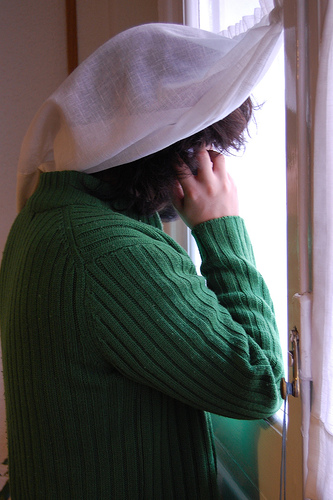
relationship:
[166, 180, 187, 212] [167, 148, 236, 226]
thumb on hand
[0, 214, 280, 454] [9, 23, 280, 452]
sweater on woman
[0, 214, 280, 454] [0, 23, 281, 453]
sweater on man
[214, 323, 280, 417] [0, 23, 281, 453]
elbow of man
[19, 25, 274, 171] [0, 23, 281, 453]
curtain over man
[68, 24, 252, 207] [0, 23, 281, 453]
head of man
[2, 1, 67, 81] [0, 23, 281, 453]
wall behind man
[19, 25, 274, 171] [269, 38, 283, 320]
drape on window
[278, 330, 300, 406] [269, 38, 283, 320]
handle on window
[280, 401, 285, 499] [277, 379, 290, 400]
ribbon on knob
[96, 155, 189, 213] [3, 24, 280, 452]
hair on person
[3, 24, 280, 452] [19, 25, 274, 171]
person under drape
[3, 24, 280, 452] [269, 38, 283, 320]
person looking out window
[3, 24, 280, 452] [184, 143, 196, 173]
person holding phone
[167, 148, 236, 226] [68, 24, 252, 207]
hand to head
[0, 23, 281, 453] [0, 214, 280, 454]
man wearing a sweater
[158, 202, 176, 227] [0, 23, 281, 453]
beard on man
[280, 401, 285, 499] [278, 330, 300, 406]
ribbon hanging from handle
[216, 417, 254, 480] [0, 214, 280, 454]
shadow from sweater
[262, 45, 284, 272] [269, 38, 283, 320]
light in window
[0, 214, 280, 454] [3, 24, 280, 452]
sweater on person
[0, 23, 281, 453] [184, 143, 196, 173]
man holding phone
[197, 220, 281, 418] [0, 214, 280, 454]
sleeve on sweater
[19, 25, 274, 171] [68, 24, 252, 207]
drape on persons head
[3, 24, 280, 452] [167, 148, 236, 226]
person holding up hand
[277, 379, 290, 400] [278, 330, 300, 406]
knob on of handle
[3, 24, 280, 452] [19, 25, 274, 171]
person standing under drape